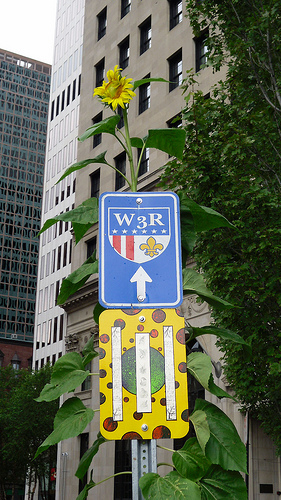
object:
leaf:
[187, 396, 249, 476]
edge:
[198, 399, 234, 424]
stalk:
[124, 114, 139, 191]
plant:
[31, 63, 250, 499]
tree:
[156, 1, 281, 456]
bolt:
[137, 197, 143, 210]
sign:
[97, 189, 183, 312]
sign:
[99, 308, 190, 440]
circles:
[151, 304, 166, 325]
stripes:
[111, 325, 177, 423]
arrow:
[128, 261, 154, 303]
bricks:
[3, 341, 35, 379]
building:
[0, 48, 53, 371]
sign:
[47, 464, 59, 485]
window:
[30, 428, 56, 499]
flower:
[92, 65, 138, 111]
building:
[25, 0, 84, 500]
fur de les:
[136, 235, 163, 257]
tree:
[0, 361, 59, 499]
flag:
[111, 234, 135, 262]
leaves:
[219, 103, 272, 198]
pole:
[131, 438, 158, 499]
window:
[38, 182, 78, 208]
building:
[55, 0, 281, 500]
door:
[108, 440, 133, 498]